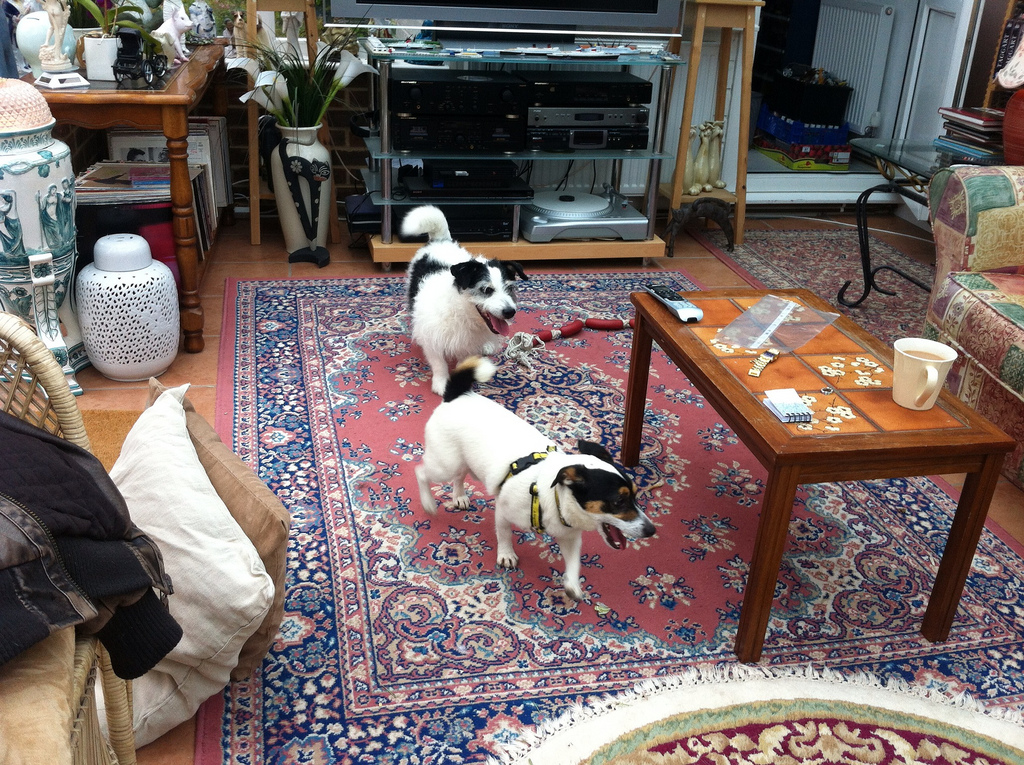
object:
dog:
[414, 355, 657, 602]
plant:
[210, 4, 397, 254]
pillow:
[131, 375, 292, 677]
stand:
[362, 39, 687, 244]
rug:
[216, 284, 366, 450]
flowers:
[317, 49, 382, 124]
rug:
[276, 405, 364, 494]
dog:
[402, 205, 530, 396]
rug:
[233, 278, 425, 765]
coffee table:
[621, 290, 1020, 664]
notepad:
[762, 388, 816, 423]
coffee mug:
[892, 338, 960, 411]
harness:
[499, 445, 557, 534]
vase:
[269, 121, 330, 254]